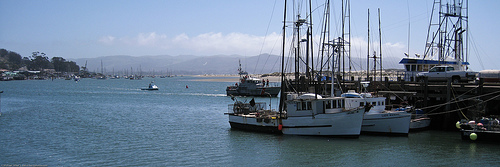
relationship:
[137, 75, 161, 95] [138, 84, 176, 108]
person on boat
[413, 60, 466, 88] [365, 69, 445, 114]
truck on dock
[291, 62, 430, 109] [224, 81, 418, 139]
dock with boats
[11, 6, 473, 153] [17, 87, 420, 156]
photo taken near water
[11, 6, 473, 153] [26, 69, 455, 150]
photo taken near water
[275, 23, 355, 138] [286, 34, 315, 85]
boat with masts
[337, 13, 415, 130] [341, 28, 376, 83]
boat with masts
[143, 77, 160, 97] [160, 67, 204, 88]
boat going out to sea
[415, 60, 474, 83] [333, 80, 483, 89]
vehicle on pier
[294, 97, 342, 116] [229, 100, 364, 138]
windows across front of boat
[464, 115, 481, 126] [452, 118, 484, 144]
floats on back of boat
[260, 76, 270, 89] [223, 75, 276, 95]
people in front of a returning boat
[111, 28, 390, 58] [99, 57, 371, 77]
clouds over mountains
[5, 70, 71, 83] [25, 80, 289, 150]
buildings near water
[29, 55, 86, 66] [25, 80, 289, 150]
trees near water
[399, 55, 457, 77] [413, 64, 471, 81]
building behind car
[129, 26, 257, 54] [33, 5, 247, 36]
clouds in sky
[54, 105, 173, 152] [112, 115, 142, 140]
water with ripples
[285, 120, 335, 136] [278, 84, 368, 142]
stripe in boat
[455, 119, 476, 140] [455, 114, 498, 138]
things on boat